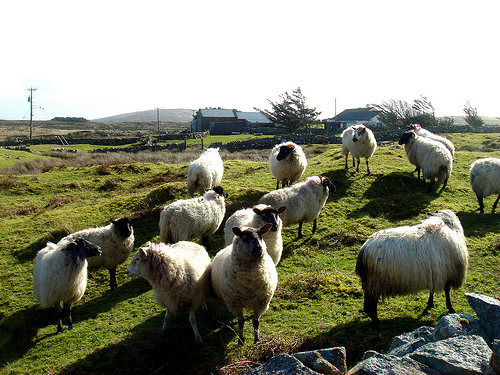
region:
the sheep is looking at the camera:
[218, 208, 314, 340]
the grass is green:
[39, 171, 105, 236]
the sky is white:
[69, 82, 171, 128]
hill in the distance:
[104, 101, 280, 151]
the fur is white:
[318, 193, 463, 303]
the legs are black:
[204, 289, 294, 346]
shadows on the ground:
[12, 282, 187, 371]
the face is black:
[54, 230, 124, 265]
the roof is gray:
[192, 100, 263, 124]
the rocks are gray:
[223, 330, 342, 370]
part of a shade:
[383, 189, 413, 211]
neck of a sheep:
[162, 273, 204, 326]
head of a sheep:
[233, 229, 265, 275]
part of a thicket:
[255, 338, 276, 359]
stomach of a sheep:
[391, 244, 428, 285]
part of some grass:
[307, 280, 342, 305]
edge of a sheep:
[320, 312, 354, 336]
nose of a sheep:
[92, 239, 111, 261]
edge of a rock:
[322, 340, 342, 364]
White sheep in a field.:
[3, 99, 485, 326]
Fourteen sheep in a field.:
[6, 115, 494, 338]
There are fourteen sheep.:
[2, 98, 492, 369]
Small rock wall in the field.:
[245, 282, 495, 367]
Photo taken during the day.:
[0, 10, 495, 360]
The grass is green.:
[0, 100, 490, 360]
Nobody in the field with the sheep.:
[0, 30, 490, 370]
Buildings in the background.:
[172, 85, 412, 130]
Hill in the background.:
[90, 100, 305, 135]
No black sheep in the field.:
[4, 85, 496, 367]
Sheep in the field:
[56, 179, 443, 337]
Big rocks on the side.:
[388, 335, 490, 370]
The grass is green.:
[351, 175, 469, 220]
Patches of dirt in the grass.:
[75, 164, 164, 221]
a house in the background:
[318, 89, 396, 135]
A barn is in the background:
[190, 105, 297, 143]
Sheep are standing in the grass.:
[92, 158, 400, 300]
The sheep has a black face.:
[33, 233, 107, 307]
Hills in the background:
[125, 99, 358, 128]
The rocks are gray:
[397, 313, 470, 369]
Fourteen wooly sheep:
[19, 78, 499, 354]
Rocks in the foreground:
[216, 306, 486, 366]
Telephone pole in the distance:
[13, 72, 69, 133]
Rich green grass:
[3, 140, 188, 228]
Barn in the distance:
[182, 97, 304, 137]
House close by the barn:
[226, 96, 416, 141]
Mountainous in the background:
[68, 100, 268, 136]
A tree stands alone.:
[252, 83, 342, 143]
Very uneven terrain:
[5, 155, 336, 275]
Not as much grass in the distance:
[7, 106, 179, 138]